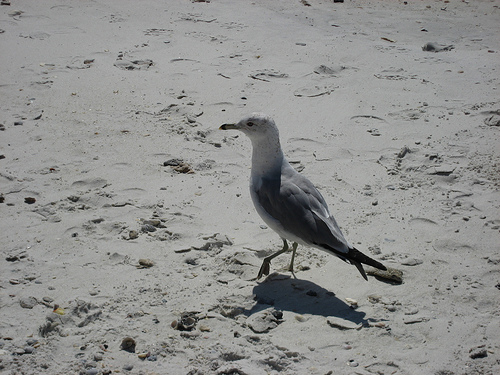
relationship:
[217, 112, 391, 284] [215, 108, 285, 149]
bird has head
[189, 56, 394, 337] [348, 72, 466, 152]
bird on sand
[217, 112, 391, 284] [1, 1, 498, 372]
bird on sand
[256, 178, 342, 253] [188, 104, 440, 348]
wing of a seagull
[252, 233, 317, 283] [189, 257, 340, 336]
feet in sand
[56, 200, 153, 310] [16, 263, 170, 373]
sand with rocks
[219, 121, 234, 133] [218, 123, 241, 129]
tip of a beak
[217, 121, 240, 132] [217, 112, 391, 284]
beak of a bird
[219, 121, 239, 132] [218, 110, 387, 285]
beak of bird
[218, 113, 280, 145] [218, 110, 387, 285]
head of bird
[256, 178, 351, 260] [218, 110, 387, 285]
wing of bird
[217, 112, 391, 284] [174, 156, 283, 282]
bird on sand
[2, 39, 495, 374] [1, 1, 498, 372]
depressions in sand